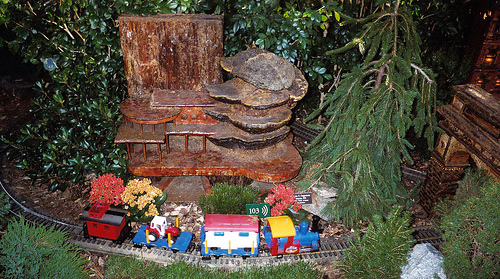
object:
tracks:
[0, 185, 488, 273]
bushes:
[438, 168, 500, 279]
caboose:
[80, 202, 131, 242]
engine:
[262, 215, 320, 259]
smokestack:
[309, 215, 324, 234]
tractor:
[144, 216, 181, 245]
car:
[132, 215, 193, 252]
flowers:
[88, 173, 125, 206]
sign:
[246, 202, 270, 217]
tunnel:
[417, 77, 500, 218]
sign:
[295, 192, 312, 204]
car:
[200, 214, 260, 261]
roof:
[204, 214, 259, 232]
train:
[80, 205, 321, 261]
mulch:
[0, 77, 89, 226]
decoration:
[112, 12, 308, 200]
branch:
[296, 1, 446, 232]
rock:
[399, 242, 447, 279]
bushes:
[333, 204, 415, 279]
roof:
[265, 215, 296, 238]